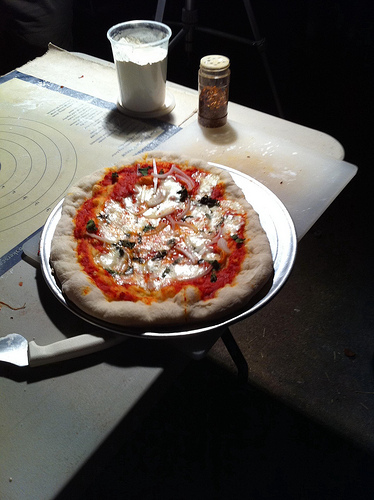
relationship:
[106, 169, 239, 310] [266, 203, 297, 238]
pizza on plate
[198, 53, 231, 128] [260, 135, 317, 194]
bottle on table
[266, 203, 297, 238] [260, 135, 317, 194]
plate on table